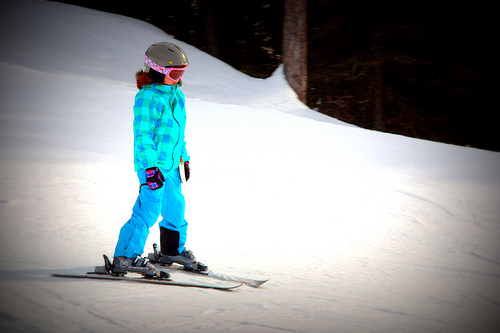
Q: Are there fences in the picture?
A: No, there are no fences.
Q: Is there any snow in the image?
A: Yes, there is snow.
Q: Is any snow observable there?
A: Yes, there is snow.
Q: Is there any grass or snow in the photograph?
A: Yes, there is snow.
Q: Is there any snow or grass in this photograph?
A: Yes, there is snow.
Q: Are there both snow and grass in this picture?
A: No, there is snow but no grass.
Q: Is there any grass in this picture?
A: No, there is no grass.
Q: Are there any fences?
A: No, there are no fences.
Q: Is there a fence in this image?
A: No, there are no fences.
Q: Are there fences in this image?
A: No, there are no fences.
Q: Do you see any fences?
A: No, there are no fences.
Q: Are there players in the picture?
A: No, there are no players.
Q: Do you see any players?
A: No, there are no players.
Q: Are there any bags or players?
A: No, there are no players or bags.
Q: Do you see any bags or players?
A: No, there are no players or bags.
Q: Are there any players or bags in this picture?
A: No, there are no players or bags.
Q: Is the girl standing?
A: Yes, the girl is standing.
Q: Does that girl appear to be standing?
A: Yes, the girl is standing.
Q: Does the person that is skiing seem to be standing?
A: Yes, the girl is standing.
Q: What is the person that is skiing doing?
A: The girl is standing.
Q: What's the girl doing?
A: The girl is standing.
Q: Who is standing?
A: The girl is standing.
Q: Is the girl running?
A: No, the girl is standing.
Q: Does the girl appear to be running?
A: No, the girl is standing.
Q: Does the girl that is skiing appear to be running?
A: No, the girl is standing.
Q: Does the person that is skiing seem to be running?
A: No, the girl is standing.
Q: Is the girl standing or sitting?
A: The girl is standing.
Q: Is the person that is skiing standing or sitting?
A: The girl is standing.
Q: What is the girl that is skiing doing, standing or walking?
A: The girl is standing.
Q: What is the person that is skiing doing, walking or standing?
A: The girl is standing.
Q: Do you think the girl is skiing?
A: Yes, the girl is skiing.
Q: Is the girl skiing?
A: Yes, the girl is skiing.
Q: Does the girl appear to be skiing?
A: Yes, the girl is skiing.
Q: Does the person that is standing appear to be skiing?
A: Yes, the girl is skiing.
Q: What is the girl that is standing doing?
A: The girl is skiing.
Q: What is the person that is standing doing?
A: The girl is skiing.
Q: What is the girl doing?
A: The girl is skiing.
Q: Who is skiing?
A: The girl is skiing.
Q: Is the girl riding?
A: No, the girl is skiing.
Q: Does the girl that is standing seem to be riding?
A: No, the girl is skiing.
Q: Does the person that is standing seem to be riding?
A: No, the girl is skiing.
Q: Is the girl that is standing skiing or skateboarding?
A: The girl is skiing.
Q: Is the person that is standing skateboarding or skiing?
A: The girl is skiing.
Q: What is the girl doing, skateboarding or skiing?
A: The girl is skiing.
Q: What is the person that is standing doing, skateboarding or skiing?
A: The girl is skiing.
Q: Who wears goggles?
A: The girl wears goggles.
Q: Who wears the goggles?
A: The girl wears goggles.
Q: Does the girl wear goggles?
A: Yes, the girl wears goggles.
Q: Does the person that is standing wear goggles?
A: Yes, the girl wears goggles.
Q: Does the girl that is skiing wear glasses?
A: No, the girl wears goggles.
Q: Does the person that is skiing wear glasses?
A: No, the girl wears goggles.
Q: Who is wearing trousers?
A: The girl is wearing trousers.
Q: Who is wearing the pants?
A: The girl is wearing trousers.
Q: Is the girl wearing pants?
A: Yes, the girl is wearing pants.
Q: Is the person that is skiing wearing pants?
A: Yes, the girl is wearing pants.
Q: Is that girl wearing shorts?
A: No, the girl is wearing pants.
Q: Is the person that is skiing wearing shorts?
A: No, the girl is wearing pants.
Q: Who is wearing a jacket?
A: The girl is wearing a jacket.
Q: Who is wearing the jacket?
A: The girl is wearing a jacket.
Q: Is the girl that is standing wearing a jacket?
A: Yes, the girl is wearing a jacket.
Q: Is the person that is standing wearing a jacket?
A: Yes, the girl is wearing a jacket.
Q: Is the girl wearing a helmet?
A: No, the girl is wearing a jacket.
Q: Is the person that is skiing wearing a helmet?
A: No, the girl is wearing a jacket.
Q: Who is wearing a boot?
A: The girl is wearing a boot.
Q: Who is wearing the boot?
A: The girl is wearing a boot.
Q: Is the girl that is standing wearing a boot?
A: Yes, the girl is wearing a boot.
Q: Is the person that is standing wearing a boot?
A: Yes, the girl is wearing a boot.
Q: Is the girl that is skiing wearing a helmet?
A: No, the girl is wearing a boot.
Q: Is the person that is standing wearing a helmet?
A: No, the girl is wearing a boot.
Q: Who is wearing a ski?
A: The girl is wearing a ski.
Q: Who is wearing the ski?
A: The girl is wearing a ski.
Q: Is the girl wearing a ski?
A: Yes, the girl is wearing a ski.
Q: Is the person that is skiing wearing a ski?
A: Yes, the girl is wearing a ski.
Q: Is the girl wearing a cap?
A: No, the girl is wearing a ski.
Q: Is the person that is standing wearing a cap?
A: No, the girl is wearing a ski.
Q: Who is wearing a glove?
A: The girl is wearing a glove.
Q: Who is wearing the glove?
A: The girl is wearing a glove.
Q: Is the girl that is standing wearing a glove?
A: Yes, the girl is wearing a glove.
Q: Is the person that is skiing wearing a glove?
A: Yes, the girl is wearing a glove.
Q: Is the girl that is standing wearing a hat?
A: No, the girl is wearing a glove.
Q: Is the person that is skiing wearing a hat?
A: No, the girl is wearing a glove.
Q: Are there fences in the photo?
A: No, there are no fences.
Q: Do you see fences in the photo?
A: No, there are no fences.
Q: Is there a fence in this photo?
A: No, there are no fences.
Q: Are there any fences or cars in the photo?
A: No, there are no fences or cars.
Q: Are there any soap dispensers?
A: No, there are no soap dispensers.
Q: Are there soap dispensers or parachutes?
A: No, there are no soap dispensers or parachutes.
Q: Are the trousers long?
A: Yes, the trousers are long.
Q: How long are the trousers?
A: The trousers are long.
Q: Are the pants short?
A: No, the pants are long.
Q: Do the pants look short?
A: No, the pants are long.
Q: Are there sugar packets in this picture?
A: No, there are no sugar packets.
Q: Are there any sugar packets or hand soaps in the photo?
A: No, there are no sugar packets or hand soaps.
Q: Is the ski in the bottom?
A: Yes, the ski is in the bottom of the image.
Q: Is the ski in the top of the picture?
A: No, the ski is in the bottom of the image.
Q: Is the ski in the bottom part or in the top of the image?
A: The ski is in the bottom of the image.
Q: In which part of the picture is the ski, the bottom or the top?
A: The ski is in the bottom of the image.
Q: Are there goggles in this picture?
A: Yes, there are goggles.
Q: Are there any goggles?
A: Yes, there are goggles.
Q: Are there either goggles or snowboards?
A: Yes, there are goggles.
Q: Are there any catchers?
A: No, there are no catchers.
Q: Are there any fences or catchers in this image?
A: No, there are no catchers or fences.